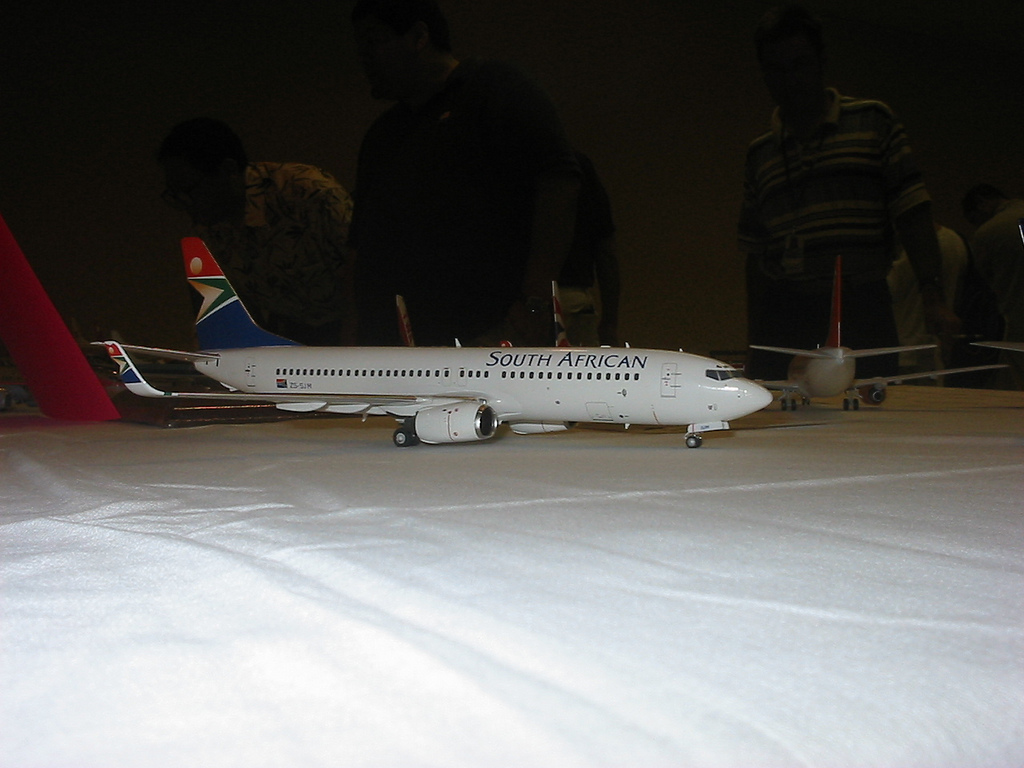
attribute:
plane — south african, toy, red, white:
[89, 215, 903, 458]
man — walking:
[716, 37, 980, 337]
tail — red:
[148, 202, 296, 356]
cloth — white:
[65, 520, 396, 657]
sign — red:
[23, 265, 198, 491]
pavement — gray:
[671, 448, 890, 520]